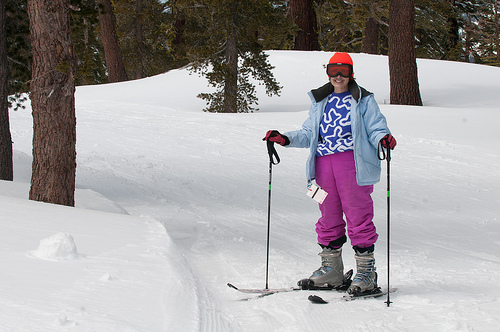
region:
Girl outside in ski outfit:
[217, 36, 428, 322]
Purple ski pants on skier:
[305, 148, 388, 265]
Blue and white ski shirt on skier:
[307, 94, 369, 160]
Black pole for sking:
[248, 131, 278, 291]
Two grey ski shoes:
[296, 236, 386, 303]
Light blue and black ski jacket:
[267, 83, 399, 185]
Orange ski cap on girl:
[322, 43, 357, 68]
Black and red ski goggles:
[322, 64, 357, 81]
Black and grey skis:
[229, 280, 409, 318]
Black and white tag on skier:
[291, 171, 336, 214]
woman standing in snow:
[172, 0, 497, 326]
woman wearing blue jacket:
[254, 84, 401, 192]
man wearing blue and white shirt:
[297, 84, 382, 161]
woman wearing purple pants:
[298, 142, 403, 255]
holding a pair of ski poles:
[198, 111, 430, 316]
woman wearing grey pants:
[292, 233, 388, 297]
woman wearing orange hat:
[318, 43, 362, 81]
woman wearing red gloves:
[262, 124, 409, 160]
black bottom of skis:
[222, 266, 402, 318]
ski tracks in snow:
[89, 101, 300, 298]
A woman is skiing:
[223, 44, 406, 317]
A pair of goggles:
[321, 59, 356, 83]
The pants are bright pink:
[307, 148, 382, 252]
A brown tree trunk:
[20, 1, 84, 208]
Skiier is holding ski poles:
[257, 47, 399, 310]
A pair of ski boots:
[306, 241, 380, 298]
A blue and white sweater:
[315, 90, 359, 157]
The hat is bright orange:
[325, 46, 357, 68]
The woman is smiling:
[318, 47, 360, 94]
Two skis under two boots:
[222, 245, 401, 313]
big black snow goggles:
[325, 62, 352, 79]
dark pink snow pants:
[314, 153, 374, 243]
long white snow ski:
[225, 281, 299, 296]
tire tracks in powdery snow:
[188, 268, 225, 325]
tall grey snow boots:
[308, 245, 346, 287]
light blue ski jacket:
[356, 85, 382, 182]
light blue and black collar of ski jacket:
[306, 83, 333, 103]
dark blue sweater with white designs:
[321, 96, 351, 154]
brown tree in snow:
[383, 1, 424, 106]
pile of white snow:
[31, 231, 81, 262]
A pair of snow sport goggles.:
[323, 60, 355, 82]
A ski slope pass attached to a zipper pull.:
[303, 179, 328, 206]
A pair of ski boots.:
[302, 247, 381, 292]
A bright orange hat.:
[327, 48, 353, 64]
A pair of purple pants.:
[309, 145, 377, 250]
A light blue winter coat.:
[279, 80, 392, 188]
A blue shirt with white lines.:
[315, 89, 360, 152]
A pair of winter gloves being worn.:
[261, 126, 398, 150]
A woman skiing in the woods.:
[260, 49, 394, 292]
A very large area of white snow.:
[3, 45, 493, 327]